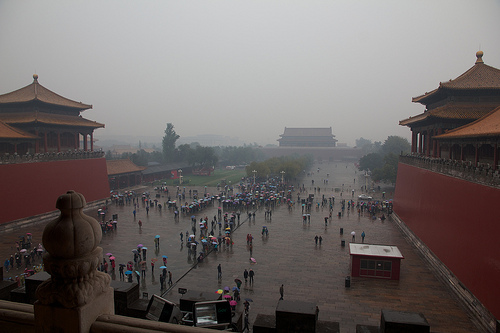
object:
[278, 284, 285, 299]
boy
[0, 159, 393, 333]
people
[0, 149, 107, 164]
wall top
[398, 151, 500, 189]
wall top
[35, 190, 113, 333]
wall top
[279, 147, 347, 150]
wall top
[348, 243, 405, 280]
building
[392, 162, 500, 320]
square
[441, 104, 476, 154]
ground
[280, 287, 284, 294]
shirt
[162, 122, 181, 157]
tree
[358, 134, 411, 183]
leaves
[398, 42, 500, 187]
building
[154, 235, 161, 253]
boy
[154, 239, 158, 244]
blue shirt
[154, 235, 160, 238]
umbrella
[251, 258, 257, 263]
umbrellas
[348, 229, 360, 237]
umbrellas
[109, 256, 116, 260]
umbrellas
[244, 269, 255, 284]
person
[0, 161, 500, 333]
road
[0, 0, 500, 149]
clouds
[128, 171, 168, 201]
boy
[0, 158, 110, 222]
square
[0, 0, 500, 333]
outside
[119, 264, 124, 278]
boy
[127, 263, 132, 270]
shirt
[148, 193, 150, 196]
shirt